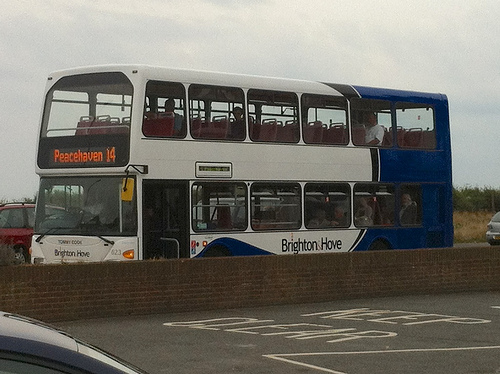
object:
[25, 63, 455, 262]
bus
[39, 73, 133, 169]
window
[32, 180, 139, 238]
windshield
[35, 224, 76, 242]
wiper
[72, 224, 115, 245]
wiper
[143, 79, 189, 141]
window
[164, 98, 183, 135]
man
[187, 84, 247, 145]
window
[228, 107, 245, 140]
woman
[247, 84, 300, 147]
window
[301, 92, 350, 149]
window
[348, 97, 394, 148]
window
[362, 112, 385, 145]
man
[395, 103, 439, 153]
window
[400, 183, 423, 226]
window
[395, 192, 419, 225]
man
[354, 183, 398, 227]
window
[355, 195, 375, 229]
woman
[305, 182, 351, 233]
window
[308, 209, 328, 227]
woman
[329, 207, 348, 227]
man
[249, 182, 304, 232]
window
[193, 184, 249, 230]
window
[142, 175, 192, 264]
door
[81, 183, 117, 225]
man